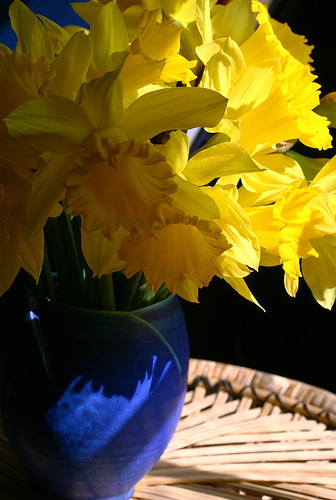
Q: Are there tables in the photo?
A: Yes, there is a table.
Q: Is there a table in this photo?
A: Yes, there is a table.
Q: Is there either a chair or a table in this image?
A: Yes, there is a table.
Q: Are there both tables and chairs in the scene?
A: No, there is a table but no chairs.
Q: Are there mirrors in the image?
A: No, there are no mirrors.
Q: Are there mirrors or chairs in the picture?
A: No, there are no mirrors or chairs.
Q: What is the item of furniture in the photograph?
A: The piece of furniture is a table.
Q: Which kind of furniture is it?
A: The piece of furniture is a table.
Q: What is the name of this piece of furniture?
A: This is a table.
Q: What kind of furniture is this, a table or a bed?
A: This is a table.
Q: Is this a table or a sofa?
A: This is a table.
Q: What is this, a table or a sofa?
A: This is a table.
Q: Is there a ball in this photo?
A: No, there are no balls.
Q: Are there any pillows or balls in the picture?
A: No, there are no balls or pillows.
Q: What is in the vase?
A: The flowers are in the vase.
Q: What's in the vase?
A: The flowers are in the vase.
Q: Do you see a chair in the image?
A: No, there are no chairs.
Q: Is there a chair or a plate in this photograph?
A: No, there are no chairs or plates.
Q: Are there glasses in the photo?
A: No, there are no glasses.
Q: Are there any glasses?
A: No, there are no glasses.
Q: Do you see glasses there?
A: No, there are no glasses.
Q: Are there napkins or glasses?
A: No, there are no glasses or napkins.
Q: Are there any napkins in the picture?
A: No, there are no napkins.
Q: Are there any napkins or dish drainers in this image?
A: No, there are no napkins or dish drainers.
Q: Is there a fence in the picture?
A: No, there are no fences.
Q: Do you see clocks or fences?
A: No, there are no fences or clocks.